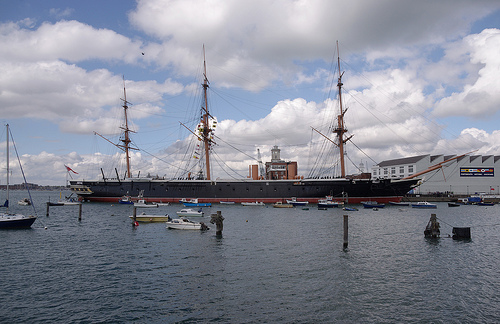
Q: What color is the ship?
A: Black, red and white.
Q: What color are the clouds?
A: White.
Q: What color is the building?
A: White.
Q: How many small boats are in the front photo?
A: Four.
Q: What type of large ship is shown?
A: Sailing.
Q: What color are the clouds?
A: White.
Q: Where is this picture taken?
A: A port.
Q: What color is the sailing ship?
A: Red and black.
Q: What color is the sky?
A: Blue.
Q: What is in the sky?
A: Clouds.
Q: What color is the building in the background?
A: White.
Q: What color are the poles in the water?
A: Grey.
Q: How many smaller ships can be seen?
A: Eight.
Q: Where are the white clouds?
A: In the sky.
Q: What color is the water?
A: Dark blue.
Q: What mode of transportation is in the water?
A: Boats.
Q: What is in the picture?
A: Boats.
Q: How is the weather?
A: Cloudy.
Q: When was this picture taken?
A: The daytime.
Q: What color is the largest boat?
A: Black.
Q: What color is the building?
A: White.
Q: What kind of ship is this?
A: A sailing ship.